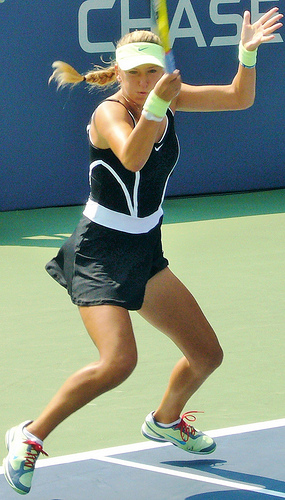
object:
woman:
[1, 3, 283, 495]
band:
[82, 196, 165, 237]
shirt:
[84, 98, 181, 236]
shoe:
[0, 419, 41, 494]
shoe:
[139, 409, 216, 454]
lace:
[22, 439, 49, 470]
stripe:
[0, 412, 284, 481]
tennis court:
[0, 188, 285, 498]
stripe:
[95, 452, 281, 498]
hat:
[112, 40, 166, 73]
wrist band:
[237, 45, 257, 67]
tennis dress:
[44, 93, 181, 311]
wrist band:
[140, 90, 170, 124]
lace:
[177, 408, 203, 442]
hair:
[47, 30, 164, 95]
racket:
[146, 1, 175, 73]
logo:
[134, 46, 148, 53]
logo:
[164, 434, 186, 448]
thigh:
[134, 262, 194, 336]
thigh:
[76, 297, 136, 339]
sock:
[155, 418, 183, 426]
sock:
[22, 428, 45, 446]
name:
[76, 0, 283, 59]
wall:
[0, 0, 285, 212]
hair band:
[82, 74, 88, 84]